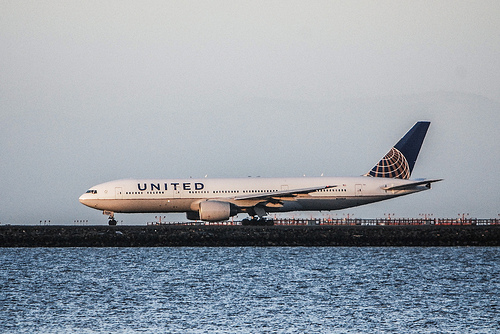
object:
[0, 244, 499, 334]
water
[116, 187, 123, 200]
door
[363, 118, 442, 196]
tail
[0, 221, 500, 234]
runway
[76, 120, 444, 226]
airplane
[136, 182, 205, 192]
writing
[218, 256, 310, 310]
wave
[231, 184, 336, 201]
wing